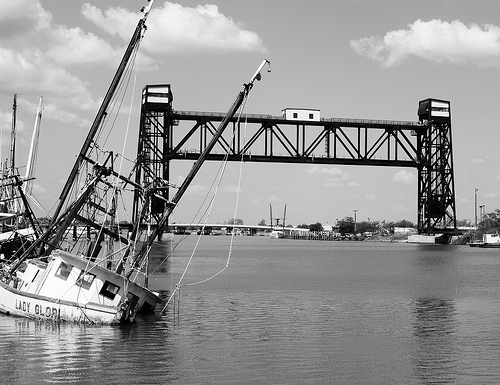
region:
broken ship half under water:
[1, 6, 271, 328]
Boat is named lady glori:
[16, 293, 64, 327]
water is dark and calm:
[1, 228, 498, 383]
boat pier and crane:
[134, 81, 459, 245]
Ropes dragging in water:
[150, 176, 222, 338]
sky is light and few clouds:
[1, 3, 495, 227]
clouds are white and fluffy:
[0, 0, 280, 125]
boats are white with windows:
[3, 248, 169, 331]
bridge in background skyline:
[107, 222, 311, 242]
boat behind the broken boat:
[0, 90, 47, 265]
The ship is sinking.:
[1, 0, 277, 350]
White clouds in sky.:
[1, 1, 498, 131]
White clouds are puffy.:
[1, 0, 499, 177]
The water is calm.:
[0, 230, 498, 383]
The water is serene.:
[0, 217, 497, 383]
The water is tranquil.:
[0, 221, 496, 383]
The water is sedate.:
[0, 224, 499, 384]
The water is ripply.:
[1, 217, 498, 383]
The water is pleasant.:
[1, 227, 499, 382]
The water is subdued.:
[0, 226, 499, 383]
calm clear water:
[0, 1, 499, 384]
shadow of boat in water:
[0, 302, 124, 372]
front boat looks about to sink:
[1, 241, 172, 330]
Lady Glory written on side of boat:
[15, 289, 72, 326]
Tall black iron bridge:
[131, 80, 460, 254]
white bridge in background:
[106, 217, 320, 241]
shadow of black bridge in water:
[126, 236, 456, 383]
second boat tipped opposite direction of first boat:
[0, 91, 41, 249]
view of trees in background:
[32, 204, 497, 252]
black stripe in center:
[137, 82, 170, 114]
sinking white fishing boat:
[1, 2, 270, 325]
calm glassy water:
[4, 227, 499, 384]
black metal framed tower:
[410, 91, 470, 237]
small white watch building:
[279, 106, 327, 127]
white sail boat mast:
[15, 94, 46, 234]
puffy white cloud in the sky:
[348, 6, 496, 81]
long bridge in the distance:
[42, 211, 319, 244]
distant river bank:
[265, 219, 412, 246]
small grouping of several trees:
[304, 209, 389, 251]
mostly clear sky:
[2, 3, 497, 239]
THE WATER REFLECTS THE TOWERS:
[2, 212, 498, 382]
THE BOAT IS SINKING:
[0, 0, 280, 380]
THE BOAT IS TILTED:
[0, 0, 275, 382]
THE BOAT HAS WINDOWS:
[24, 220, 160, 339]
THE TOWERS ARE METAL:
[128, 75, 499, 270]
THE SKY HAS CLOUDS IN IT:
[0, 0, 499, 170]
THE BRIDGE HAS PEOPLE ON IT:
[160, 96, 426, 181]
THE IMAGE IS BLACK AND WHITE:
[0, 0, 499, 384]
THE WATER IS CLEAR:
[1, 217, 498, 384]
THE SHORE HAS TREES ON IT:
[128, 202, 497, 282]